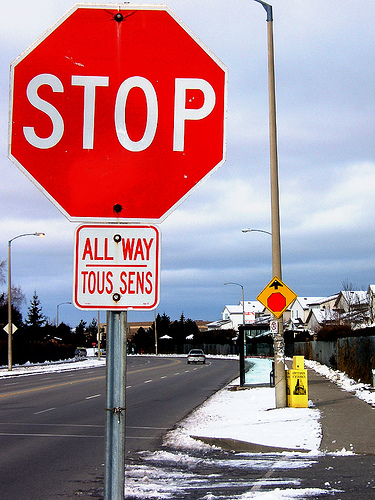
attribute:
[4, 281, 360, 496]
road — black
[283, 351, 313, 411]
stand — yellow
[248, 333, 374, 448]
sidewalk — clear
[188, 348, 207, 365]
car — silver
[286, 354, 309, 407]
dispenser — yellow, black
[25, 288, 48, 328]
tree — pointed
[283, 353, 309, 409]
machine — yellow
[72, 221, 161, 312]
square sign — red, green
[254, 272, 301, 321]
traffic sign — yellow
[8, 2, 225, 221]
sign — red, white, stop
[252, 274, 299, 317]
sign — yellow, red, black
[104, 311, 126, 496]
pole — silver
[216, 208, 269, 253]
light — off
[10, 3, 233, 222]
stop sign — red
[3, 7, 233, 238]
stop sign — white, red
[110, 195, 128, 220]
screw —  rusted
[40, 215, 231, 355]
sign — square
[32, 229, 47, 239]
steet light — on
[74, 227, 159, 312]
sign — white, red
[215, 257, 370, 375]
shelter — clear, black